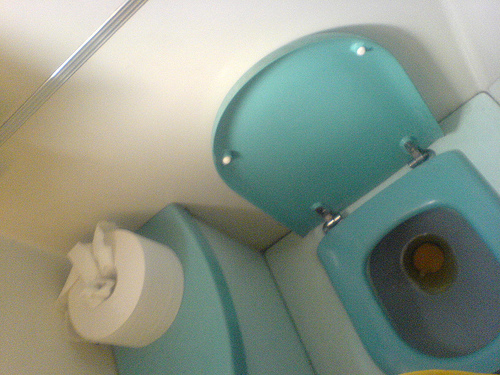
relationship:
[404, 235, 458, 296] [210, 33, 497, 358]
water in toilet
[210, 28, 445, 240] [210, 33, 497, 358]
lid up on toilet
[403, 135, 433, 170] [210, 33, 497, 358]
hinge on toilet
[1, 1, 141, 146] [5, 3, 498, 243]
trim on wall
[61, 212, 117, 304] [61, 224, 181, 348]
paper inside toilet paper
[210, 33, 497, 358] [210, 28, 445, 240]
toilet has an open lid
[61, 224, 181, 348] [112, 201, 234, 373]
toilet paper sits on a ledge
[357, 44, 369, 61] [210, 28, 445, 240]
lid guard on lid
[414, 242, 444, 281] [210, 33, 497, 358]
drain in toilet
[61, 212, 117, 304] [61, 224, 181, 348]
paper on toilet paper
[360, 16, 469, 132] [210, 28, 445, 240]
shadow of lid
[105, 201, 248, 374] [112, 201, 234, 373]
tank top used for a shelf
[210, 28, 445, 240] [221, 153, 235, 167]
lid has a lid guard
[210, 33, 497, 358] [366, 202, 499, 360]
toilet on inside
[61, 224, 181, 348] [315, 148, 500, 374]
toilet paper by seat